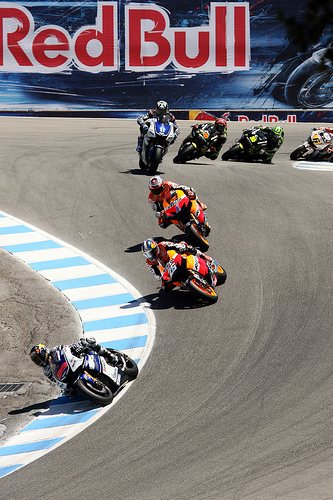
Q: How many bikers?
A: 7.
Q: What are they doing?
A: Racing.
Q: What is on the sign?
A: Red bull.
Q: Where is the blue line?
A: On the road.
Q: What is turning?
A: The bike.